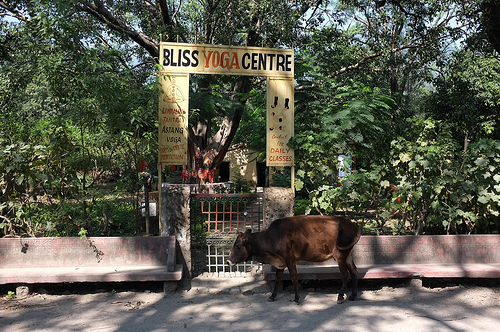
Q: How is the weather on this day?
A: It is clear.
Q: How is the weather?
A: It is clear.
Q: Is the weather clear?
A: Yes, it is clear.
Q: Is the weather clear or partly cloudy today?
A: It is clear.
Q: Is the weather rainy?
A: No, it is clear.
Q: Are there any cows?
A: Yes, there is a cow.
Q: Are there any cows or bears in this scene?
A: Yes, there is a cow.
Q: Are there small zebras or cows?
A: Yes, there is a small cow.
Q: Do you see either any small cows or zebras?
A: Yes, there is a small cow.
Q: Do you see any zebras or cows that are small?
A: Yes, the cow is small.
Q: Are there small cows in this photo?
A: Yes, there is a small cow.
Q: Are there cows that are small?
A: Yes, there is a cow that is small.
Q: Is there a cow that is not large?
A: Yes, there is a small cow.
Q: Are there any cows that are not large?
A: Yes, there is a small cow.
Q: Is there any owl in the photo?
A: No, there are no owls.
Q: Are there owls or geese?
A: No, there are no owls or geese.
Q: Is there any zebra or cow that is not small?
A: No, there is a cow but it is small.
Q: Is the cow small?
A: Yes, the cow is small.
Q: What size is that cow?
A: The cow is small.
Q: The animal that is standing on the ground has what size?
A: The cow is small.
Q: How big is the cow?
A: The cow is small.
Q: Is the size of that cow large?
A: No, the cow is small.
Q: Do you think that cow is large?
A: No, the cow is small.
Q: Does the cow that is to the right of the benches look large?
A: No, the cow is small.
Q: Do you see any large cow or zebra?
A: No, there is a cow but it is small.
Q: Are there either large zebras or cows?
A: No, there is a cow but it is small.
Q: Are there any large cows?
A: No, there is a cow but it is small.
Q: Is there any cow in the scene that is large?
A: No, there is a cow but it is small.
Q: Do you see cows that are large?
A: No, there is a cow but it is small.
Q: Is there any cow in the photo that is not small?
A: No, there is a cow but it is small.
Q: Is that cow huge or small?
A: The cow is small.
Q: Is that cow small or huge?
A: The cow is small.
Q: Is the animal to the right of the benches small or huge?
A: The cow is small.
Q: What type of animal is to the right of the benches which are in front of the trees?
A: The animal is a cow.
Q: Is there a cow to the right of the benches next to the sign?
A: Yes, there is a cow to the right of the benches.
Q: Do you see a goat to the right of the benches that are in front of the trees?
A: No, there is a cow to the right of the benches.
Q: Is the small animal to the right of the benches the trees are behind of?
A: Yes, the cow is to the right of the benches.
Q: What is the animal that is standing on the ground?
A: The animal is a cow.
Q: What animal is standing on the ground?
A: The animal is a cow.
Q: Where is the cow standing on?
A: The cow is standing on the ground.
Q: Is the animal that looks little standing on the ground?
A: Yes, the cow is standing on the ground.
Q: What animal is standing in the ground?
A: The animal is a cow.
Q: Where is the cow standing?
A: The cow is standing in the ground.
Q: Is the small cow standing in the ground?
A: Yes, the cow is standing in the ground.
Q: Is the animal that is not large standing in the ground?
A: Yes, the cow is standing in the ground.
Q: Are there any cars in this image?
A: No, there are no cars.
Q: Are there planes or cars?
A: No, there are no cars or planes.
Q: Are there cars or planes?
A: No, there are no cars or planes.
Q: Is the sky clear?
A: Yes, the sky is clear.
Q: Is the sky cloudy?
A: No, the sky is clear.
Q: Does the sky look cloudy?
A: No, the sky is clear.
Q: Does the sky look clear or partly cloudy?
A: The sky is clear.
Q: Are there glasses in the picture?
A: No, there are no glasses.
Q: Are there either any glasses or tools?
A: No, there are no glasses or tools.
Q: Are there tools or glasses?
A: No, there are no glasses or tools.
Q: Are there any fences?
A: Yes, there is a fence.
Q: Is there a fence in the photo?
A: Yes, there is a fence.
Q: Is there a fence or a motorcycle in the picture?
A: Yes, there is a fence.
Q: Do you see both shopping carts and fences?
A: No, there is a fence but no shopping carts.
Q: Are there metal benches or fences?
A: Yes, there is a metal fence.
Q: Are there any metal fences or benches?
A: Yes, there is a metal fence.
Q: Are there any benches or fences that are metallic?
A: Yes, the fence is metallic.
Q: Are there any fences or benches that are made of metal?
A: Yes, the fence is made of metal.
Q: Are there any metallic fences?
A: Yes, there is a metal fence.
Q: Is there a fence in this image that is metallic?
A: Yes, there is a fence that is metallic.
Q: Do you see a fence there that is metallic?
A: Yes, there is a fence that is metallic.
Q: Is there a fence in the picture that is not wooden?
A: Yes, there is a metallic fence.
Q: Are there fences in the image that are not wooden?
A: Yes, there is a metallic fence.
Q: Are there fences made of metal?
A: Yes, there is a fence that is made of metal.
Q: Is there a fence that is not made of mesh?
A: Yes, there is a fence that is made of metal.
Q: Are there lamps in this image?
A: No, there are no lamps.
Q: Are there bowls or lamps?
A: No, there are no lamps or bowls.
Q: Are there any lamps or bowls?
A: No, there are no lamps or bowls.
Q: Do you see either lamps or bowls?
A: No, there are no lamps or bowls.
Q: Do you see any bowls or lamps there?
A: No, there are no lamps or bowls.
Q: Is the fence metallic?
A: Yes, the fence is metallic.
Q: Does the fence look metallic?
A: Yes, the fence is metallic.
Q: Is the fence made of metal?
A: Yes, the fence is made of metal.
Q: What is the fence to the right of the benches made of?
A: The fence is made of metal.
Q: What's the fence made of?
A: The fence is made of metal.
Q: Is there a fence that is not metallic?
A: No, there is a fence but it is metallic.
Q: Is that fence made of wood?
A: No, the fence is made of metal.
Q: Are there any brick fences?
A: No, there is a fence but it is made of metal.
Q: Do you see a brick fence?
A: No, there is a fence but it is made of metal.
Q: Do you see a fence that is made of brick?
A: No, there is a fence but it is made of metal.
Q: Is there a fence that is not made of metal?
A: No, there is a fence but it is made of metal.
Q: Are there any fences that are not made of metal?
A: No, there is a fence but it is made of metal.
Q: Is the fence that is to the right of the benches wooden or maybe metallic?
A: The fence is metallic.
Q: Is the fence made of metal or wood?
A: The fence is made of metal.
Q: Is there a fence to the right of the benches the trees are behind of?
A: Yes, there is a fence to the right of the benches.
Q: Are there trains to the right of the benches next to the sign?
A: No, there is a fence to the right of the benches.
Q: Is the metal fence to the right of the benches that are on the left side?
A: Yes, the fence is to the right of the benches.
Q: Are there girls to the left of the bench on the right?
A: No, there is a fence to the left of the bench.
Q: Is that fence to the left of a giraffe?
A: No, the fence is to the left of the bench.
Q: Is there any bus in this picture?
A: No, there are no buses.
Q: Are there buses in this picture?
A: No, there are no buses.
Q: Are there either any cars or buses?
A: No, there are no buses or cars.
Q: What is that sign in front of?
A: The sign is in front of the trees.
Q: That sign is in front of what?
A: The sign is in front of the trees.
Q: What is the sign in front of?
A: The sign is in front of the trees.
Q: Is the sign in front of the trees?
A: Yes, the sign is in front of the trees.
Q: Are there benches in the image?
A: Yes, there is a bench.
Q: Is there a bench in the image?
A: Yes, there is a bench.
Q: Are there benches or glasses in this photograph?
A: Yes, there is a bench.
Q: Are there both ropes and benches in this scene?
A: No, there is a bench but no ropes.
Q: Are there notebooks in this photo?
A: No, there are no notebooks.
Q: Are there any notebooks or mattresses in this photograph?
A: No, there are no notebooks or mattresses.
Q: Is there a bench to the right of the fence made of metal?
A: Yes, there is a bench to the right of the fence.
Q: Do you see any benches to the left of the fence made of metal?
A: No, the bench is to the right of the fence.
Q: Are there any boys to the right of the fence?
A: No, there is a bench to the right of the fence.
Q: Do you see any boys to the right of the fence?
A: No, there is a bench to the right of the fence.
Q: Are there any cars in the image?
A: No, there are no cars.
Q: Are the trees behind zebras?
A: No, the trees are behind the benches.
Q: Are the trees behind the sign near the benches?
A: Yes, the trees are behind the sign.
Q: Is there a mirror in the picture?
A: No, there are no mirrors.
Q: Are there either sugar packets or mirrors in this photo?
A: No, there are no mirrors or sugar packets.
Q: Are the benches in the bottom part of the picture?
A: Yes, the benches are in the bottom of the image.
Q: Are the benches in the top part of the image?
A: No, the benches are in the bottom of the image.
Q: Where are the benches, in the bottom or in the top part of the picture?
A: The benches are in the bottom of the image.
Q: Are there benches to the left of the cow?
A: Yes, there are benches to the left of the cow.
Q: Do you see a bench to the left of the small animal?
A: Yes, there are benches to the left of the cow.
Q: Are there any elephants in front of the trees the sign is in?
A: No, there are benches in front of the trees.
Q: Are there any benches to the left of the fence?
A: Yes, there are benches to the left of the fence.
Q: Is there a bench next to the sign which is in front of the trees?
A: Yes, there are benches next to the sign.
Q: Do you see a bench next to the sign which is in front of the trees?
A: Yes, there are benches next to the sign.